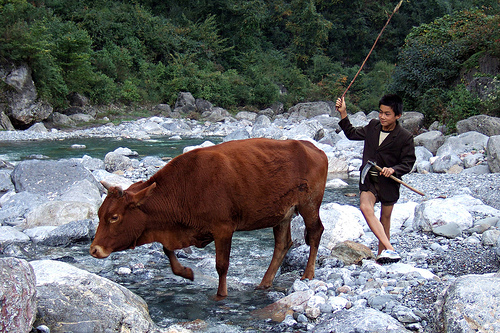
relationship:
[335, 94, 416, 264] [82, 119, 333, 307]
boy chasing cow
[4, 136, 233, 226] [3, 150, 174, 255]
water rushing over rocks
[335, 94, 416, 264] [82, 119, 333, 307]
boy behind cow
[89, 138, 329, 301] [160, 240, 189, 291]
brown cow has leg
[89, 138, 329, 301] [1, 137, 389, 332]
brown cow crossing water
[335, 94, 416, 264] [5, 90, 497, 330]
boy on rocks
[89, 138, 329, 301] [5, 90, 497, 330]
brown cow on rocks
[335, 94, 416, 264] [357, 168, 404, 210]
boy wearing pants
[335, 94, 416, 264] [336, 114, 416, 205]
boy wearing clothing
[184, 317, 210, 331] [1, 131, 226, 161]
pebble near pond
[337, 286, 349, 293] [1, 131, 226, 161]
pebble near pond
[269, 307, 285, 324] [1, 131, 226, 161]
pebble near pond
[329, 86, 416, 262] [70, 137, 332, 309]
boy smiling at cow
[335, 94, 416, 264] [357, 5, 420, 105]
boy holding stick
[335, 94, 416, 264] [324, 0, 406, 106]
boy holding whip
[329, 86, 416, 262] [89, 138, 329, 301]
boy and brown cow